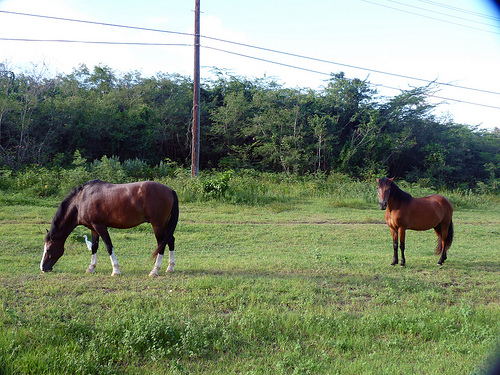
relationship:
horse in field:
[37, 178, 182, 281] [7, 84, 499, 369]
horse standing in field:
[37, 178, 182, 281] [7, 84, 499, 369]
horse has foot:
[37, 178, 182, 281] [107, 268, 126, 276]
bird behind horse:
[80, 234, 98, 254] [37, 178, 182, 281]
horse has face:
[37, 178, 182, 281] [37, 237, 72, 273]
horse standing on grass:
[37, 178, 182, 281] [13, 297, 496, 371]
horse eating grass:
[37, 178, 182, 281] [13, 297, 496, 371]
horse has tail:
[37, 178, 182, 281] [149, 187, 192, 260]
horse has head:
[37, 178, 182, 281] [42, 227, 68, 267]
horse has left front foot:
[37, 178, 182, 281] [93, 221, 127, 279]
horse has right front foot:
[37, 178, 182, 281] [81, 211, 101, 273]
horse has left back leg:
[37, 178, 182, 281] [147, 217, 166, 280]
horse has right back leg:
[37, 178, 182, 281] [162, 226, 179, 276]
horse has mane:
[37, 178, 182, 281] [38, 184, 77, 237]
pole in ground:
[181, 0, 209, 180] [16, 174, 494, 215]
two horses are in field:
[37, 162, 465, 271] [7, 84, 499, 369]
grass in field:
[13, 297, 496, 371] [7, 84, 499, 369]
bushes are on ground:
[12, 166, 499, 205] [16, 174, 494, 215]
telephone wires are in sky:
[8, 13, 495, 108] [1, 2, 500, 122]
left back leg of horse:
[147, 217, 166, 280] [37, 178, 182, 281]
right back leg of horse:
[162, 226, 179, 276] [37, 178, 182, 281]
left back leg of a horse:
[147, 217, 166, 280] [37, 178, 182, 281]